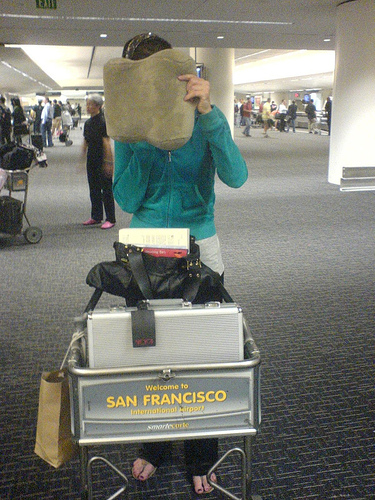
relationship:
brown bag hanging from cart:
[29, 363, 76, 471] [47, 304, 269, 498]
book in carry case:
[114, 226, 193, 259] [88, 302, 242, 369]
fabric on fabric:
[111, 102, 251, 237] [111, 102, 248, 242]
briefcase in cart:
[85, 297, 245, 367] [69, 235, 267, 498]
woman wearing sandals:
[80, 25, 273, 495] [127, 457, 228, 495]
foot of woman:
[130, 456, 157, 480] [110, 31, 249, 494]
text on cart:
[105, 379, 234, 430] [66, 282, 262, 497]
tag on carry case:
[129, 302, 157, 348] [88, 302, 242, 369]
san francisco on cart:
[101, 389, 227, 409] [69, 308, 261, 497]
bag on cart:
[70, 221, 243, 319] [69, 308, 261, 497]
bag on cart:
[85, 227, 234, 317] [66, 282, 262, 497]